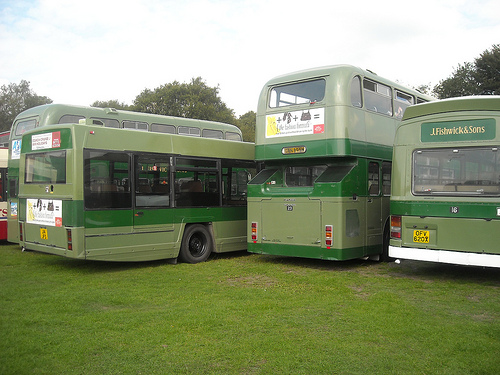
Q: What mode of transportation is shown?
A: Buses.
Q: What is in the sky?
A: Clouds.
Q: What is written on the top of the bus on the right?
A: J. Fishwikk & Sons.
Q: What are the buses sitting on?
A: Grass.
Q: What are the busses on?
A: Grass.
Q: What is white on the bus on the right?
A: Bumper.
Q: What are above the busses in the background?
A: Trees.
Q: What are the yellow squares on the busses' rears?
A: License plates.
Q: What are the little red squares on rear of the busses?
A: Brake lights.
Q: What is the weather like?
A: Cloudy.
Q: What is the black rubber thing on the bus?
A: Tire.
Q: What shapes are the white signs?
A: Rectangles.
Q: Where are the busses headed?
A: They are parked.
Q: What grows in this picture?
A: Grass and trees.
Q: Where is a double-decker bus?
A: Between two regular buses.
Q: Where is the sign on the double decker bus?
A: Upper level back.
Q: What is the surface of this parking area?
A: Grass.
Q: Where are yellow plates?
A: Back of two regular buses.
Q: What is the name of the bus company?
A: J Fishwick & Sons.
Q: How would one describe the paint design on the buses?
A: Two tone green and green.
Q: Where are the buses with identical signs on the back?
A: Second from right and third from right.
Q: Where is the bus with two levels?
A: Second from right.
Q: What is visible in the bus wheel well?
A: Tire.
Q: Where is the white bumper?
A: Bus on right.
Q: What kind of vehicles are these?
A: Buses.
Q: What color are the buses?
A: Green.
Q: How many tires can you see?
A: 1.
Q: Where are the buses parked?
A: In the grass.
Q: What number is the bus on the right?
A: 16.